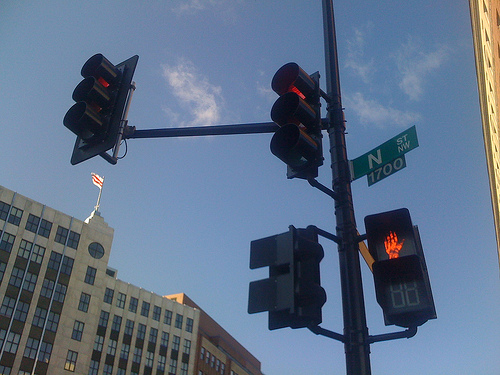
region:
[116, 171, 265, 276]
blue sky is clear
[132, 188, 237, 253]
blue sky is clear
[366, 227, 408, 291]
the light is orange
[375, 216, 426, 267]
the light is orange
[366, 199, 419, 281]
the light is orange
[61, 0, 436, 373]
A large black pole containing traffic lights and street signs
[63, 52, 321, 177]
Two traffic lights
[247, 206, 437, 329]
Two pedestrian crossing signals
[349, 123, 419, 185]
A street sign reading N St NW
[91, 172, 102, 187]
A red and white flag blowing in the wind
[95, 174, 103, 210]
A silver flag pole on the top of a large building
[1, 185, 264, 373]
A large, multi-story building resembling a university department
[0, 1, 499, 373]
A blue sky with light cloud coverage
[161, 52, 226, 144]
A small wispy cloud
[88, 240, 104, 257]
A decorative, circular window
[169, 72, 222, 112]
white cloud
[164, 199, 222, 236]
the sky is clear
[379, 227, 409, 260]
a hand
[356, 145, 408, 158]
a street sign that is green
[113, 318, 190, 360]
windows on the building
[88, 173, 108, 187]
a flag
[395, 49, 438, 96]
the white clouds in the sky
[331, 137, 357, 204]
a pole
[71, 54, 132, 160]
a traffic signal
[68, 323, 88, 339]
a window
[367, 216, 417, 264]
Red hand traffic signal.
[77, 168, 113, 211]
Flag on the pole.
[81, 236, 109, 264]
circle window on the building.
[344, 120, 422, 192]
Green street sign.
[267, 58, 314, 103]
Red light on traffic signal.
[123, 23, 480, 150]
White clouds in the sky.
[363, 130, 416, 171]
White lettering on the sign.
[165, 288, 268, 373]
Red building in the background.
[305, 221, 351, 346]
Bracket holding traffic signal.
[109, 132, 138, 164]
Wire on traffic signal.